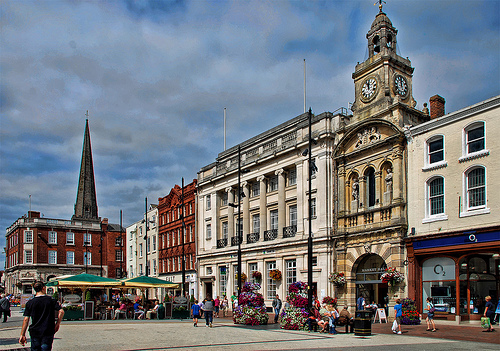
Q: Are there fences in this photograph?
A: No, there are no fences.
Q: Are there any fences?
A: No, there are no fences.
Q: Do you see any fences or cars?
A: No, there are no fences or cars.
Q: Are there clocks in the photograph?
A: Yes, there is a clock.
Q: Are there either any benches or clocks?
A: Yes, there is a clock.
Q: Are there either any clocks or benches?
A: Yes, there is a clock.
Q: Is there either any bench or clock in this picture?
A: Yes, there is a clock.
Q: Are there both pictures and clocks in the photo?
A: No, there is a clock but no pictures.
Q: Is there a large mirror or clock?
A: Yes, there is a large clock.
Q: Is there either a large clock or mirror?
A: Yes, there is a large clock.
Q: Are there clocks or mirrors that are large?
A: Yes, the clock is large.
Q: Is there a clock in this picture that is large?
A: Yes, there is a clock that is large.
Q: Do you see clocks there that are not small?
A: Yes, there is a large clock.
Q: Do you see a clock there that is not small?
A: Yes, there is a large clock.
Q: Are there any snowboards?
A: No, there are no snowboards.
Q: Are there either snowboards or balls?
A: No, there are no snowboards or balls.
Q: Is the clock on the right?
A: Yes, the clock is on the right of the image.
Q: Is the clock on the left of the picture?
A: No, the clock is on the right of the image.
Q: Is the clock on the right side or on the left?
A: The clock is on the right of the image.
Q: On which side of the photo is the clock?
A: The clock is on the right of the image.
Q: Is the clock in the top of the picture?
A: Yes, the clock is in the top of the image.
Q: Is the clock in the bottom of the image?
A: No, the clock is in the top of the image.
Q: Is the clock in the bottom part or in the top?
A: The clock is in the top of the image.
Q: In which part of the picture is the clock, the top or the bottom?
A: The clock is in the top of the image.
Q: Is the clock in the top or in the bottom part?
A: The clock is in the top of the image.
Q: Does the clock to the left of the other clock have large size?
A: Yes, the clock is large.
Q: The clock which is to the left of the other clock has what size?
A: The clock is large.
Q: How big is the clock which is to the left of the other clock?
A: The clock is large.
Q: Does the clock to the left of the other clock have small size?
A: No, the clock is large.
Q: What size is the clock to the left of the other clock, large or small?
A: The clock is large.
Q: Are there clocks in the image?
A: Yes, there is a clock.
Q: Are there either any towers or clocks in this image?
A: Yes, there is a clock.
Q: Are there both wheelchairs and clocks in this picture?
A: No, there is a clock but no wheelchairs.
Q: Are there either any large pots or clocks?
A: Yes, there is a large clock.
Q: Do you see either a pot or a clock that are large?
A: Yes, the clock is large.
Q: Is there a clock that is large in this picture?
A: Yes, there is a large clock.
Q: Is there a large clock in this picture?
A: Yes, there is a large clock.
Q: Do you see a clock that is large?
A: Yes, there is a clock that is large.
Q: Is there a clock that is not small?
A: Yes, there is a large clock.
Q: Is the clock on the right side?
A: Yes, the clock is on the right of the image.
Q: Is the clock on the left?
A: No, the clock is on the right of the image.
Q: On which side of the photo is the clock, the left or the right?
A: The clock is on the right of the image.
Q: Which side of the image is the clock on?
A: The clock is on the right of the image.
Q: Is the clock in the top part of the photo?
A: Yes, the clock is in the top of the image.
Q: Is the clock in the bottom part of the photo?
A: No, the clock is in the top of the image.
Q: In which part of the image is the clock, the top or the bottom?
A: The clock is in the top of the image.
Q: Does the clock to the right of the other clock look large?
A: Yes, the clock is large.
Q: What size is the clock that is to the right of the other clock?
A: The clock is large.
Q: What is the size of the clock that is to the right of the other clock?
A: The clock is large.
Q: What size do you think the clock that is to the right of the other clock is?
A: The clock is large.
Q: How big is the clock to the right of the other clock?
A: The clock is large.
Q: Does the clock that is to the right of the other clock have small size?
A: No, the clock is large.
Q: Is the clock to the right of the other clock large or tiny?
A: The clock is large.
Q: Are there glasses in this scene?
A: No, there are no glasses.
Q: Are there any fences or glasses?
A: No, there are no glasses or fences.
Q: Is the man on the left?
A: Yes, the man is on the left of the image.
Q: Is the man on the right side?
A: No, the man is on the left of the image.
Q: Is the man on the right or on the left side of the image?
A: The man is on the left of the image.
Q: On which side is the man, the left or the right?
A: The man is on the left of the image.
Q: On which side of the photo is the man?
A: The man is on the left of the image.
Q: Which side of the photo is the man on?
A: The man is on the left of the image.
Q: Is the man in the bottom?
A: Yes, the man is in the bottom of the image.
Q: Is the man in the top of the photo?
A: No, the man is in the bottom of the image.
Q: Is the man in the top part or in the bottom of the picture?
A: The man is in the bottom of the image.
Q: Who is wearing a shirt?
A: The man is wearing a shirt.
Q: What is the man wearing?
A: The man is wearing a shirt.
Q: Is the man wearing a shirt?
A: Yes, the man is wearing a shirt.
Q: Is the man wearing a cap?
A: No, the man is wearing a shirt.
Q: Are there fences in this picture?
A: No, there are no fences.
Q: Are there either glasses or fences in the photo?
A: No, there are no fences or glasses.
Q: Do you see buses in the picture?
A: No, there are no buses.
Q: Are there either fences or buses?
A: No, there are no buses or fences.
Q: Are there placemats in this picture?
A: No, there are no placemats.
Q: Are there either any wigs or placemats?
A: No, there are no placemats or wigs.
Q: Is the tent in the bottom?
A: Yes, the tent is in the bottom of the image.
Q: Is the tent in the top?
A: No, the tent is in the bottom of the image.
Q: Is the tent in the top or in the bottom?
A: The tent is in the bottom of the image.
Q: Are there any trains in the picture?
A: No, there are no trains.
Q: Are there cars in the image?
A: No, there are no cars.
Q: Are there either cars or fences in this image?
A: No, there are no cars or fences.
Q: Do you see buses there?
A: No, there are no buses.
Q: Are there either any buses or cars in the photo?
A: No, there are no buses or cars.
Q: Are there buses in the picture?
A: No, there are no buses.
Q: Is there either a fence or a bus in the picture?
A: No, there are no buses or fences.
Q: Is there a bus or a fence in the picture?
A: No, there are no buses or fences.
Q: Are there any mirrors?
A: No, there are no mirrors.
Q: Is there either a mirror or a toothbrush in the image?
A: No, there are no mirrors or toothbrushes.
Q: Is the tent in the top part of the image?
A: No, the tent is in the bottom of the image.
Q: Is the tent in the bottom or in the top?
A: The tent is in the bottom of the image.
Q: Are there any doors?
A: Yes, there is a door.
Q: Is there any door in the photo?
A: Yes, there is a door.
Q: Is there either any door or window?
A: Yes, there is a door.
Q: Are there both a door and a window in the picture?
A: Yes, there are both a door and a window.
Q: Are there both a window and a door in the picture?
A: Yes, there are both a door and a window.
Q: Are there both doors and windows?
A: Yes, there are both a door and a window.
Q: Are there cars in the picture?
A: No, there are no cars.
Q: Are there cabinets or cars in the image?
A: No, there are no cars or cabinets.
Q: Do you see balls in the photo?
A: No, there are no balls.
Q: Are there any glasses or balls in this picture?
A: No, there are no balls or glasses.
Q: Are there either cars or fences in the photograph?
A: No, there are no fences or cars.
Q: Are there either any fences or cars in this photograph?
A: No, there are no fences or cars.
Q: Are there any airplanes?
A: No, there are no airplanes.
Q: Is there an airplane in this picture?
A: No, there are no airplanes.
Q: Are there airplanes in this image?
A: No, there are no airplanes.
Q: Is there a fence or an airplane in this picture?
A: No, there are no airplanes or fences.